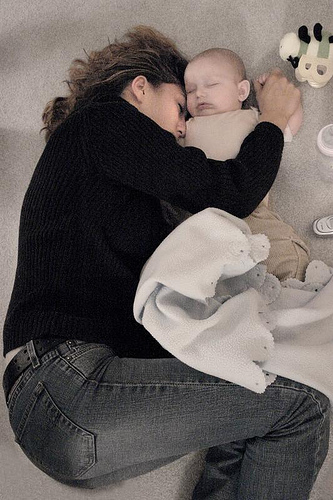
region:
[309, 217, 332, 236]
part of a baby's shoe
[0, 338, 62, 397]
part of a woman's black belt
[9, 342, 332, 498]
the leg of a woman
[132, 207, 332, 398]
a baby blanket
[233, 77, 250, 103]
the ear of a baby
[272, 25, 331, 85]
an animal baby toy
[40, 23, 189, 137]
a woman's brown hair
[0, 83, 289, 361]
a woman's black shirt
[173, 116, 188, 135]
the nose of a woman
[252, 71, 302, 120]
the hand of a woman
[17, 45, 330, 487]
a mom sleeping with her baby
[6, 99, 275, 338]
a woman in a black shirt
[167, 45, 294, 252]
a beautiful baby sleeping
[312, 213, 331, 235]
part of the baby white shoe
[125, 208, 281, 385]
the baby white cloth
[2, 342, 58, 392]
a black belt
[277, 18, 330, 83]
a baby toy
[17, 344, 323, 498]
a woman in a sexy jeans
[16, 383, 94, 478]
the jeans rear pocket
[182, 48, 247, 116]
the head of the baby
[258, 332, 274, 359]
eyelet cut out on a blanket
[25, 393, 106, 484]
the back pocket on jeans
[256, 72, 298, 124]
a hand holding a baby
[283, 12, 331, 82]
a stuffed toy next to the baby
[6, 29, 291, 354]
a woman wearing a black sweater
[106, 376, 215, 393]
stitching on the jeans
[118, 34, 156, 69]
dark brown hair on a head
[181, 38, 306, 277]
a sleeping baby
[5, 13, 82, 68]
gray carpet on the floor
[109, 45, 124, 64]
hair of a lady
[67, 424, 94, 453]
edge of a pocket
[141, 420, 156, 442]
part of a jeans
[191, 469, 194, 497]
edge of a shade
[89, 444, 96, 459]
edge of a pocket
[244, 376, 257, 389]
edge of a towel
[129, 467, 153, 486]
part of a shade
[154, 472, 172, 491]
part of a floor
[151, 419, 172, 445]
part of a thigh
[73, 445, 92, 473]
part of a pocket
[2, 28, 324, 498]
woman sleeping with baby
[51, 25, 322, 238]
woman holding baby's hand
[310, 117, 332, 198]
baby bottle laying on floor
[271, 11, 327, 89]
baby toy laying on floor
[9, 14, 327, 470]
woman wearing black sweater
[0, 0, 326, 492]
woman wearing black jeans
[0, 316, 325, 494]
black belt on jeans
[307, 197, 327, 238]
shoe laying on floor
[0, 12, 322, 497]
woman with brown hair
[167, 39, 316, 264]
baby sleeping peacefully